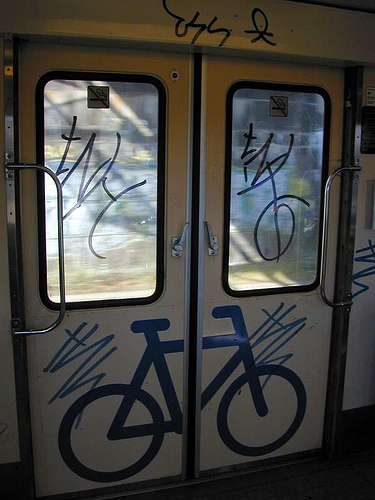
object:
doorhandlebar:
[4, 162, 66, 337]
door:
[13, 48, 348, 495]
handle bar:
[211, 304, 243, 319]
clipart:
[43, 301, 307, 483]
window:
[42, 72, 172, 303]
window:
[224, 79, 326, 295]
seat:
[130, 314, 172, 336]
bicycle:
[53, 298, 308, 483]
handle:
[170, 221, 192, 257]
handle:
[318, 164, 363, 309]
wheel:
[56, 380, 166, 484]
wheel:
[216, 360, 309, 459]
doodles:
[54, 115, 148, 256]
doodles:
[245, 298, 305, 391]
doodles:
[43, 320, 116, 429]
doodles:
[159, 0, 274, 45]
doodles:
[236, 119, 311, 269]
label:
[269, 95, 290, 117]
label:
[87, 85, 109, 107]